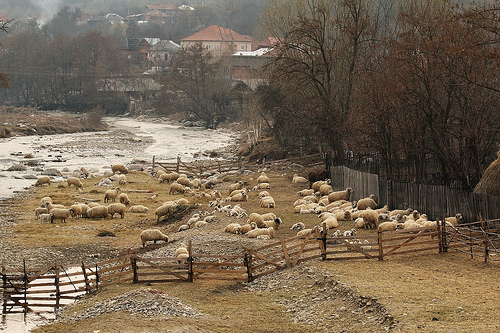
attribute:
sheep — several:
[29, 170, 54, 188]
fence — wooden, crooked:
[0, 219, 498, 312]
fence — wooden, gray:
[329, 162, 496, 222]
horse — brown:
[291, 161, 322, 192]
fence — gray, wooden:
[348, 162, 443, 210]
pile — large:
[61, 281, 207, 326]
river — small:
[1, 112, 241, 184]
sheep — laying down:
[227, 218, 238, 238]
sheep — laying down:
[191, 218, 210, 229]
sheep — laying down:
[224, 186, 247, 197]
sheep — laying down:
[341, 225, 351, 236]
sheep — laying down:
[291, 201, 314, 214]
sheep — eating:
[47, 208, 75, 226]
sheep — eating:
[99, 185, 117, 198]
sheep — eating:
[118, 190, 132, 208]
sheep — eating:
[153, 200, 178, 216]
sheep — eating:
[65, 173, 81, 186]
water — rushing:
[14, 105, 238, 202]